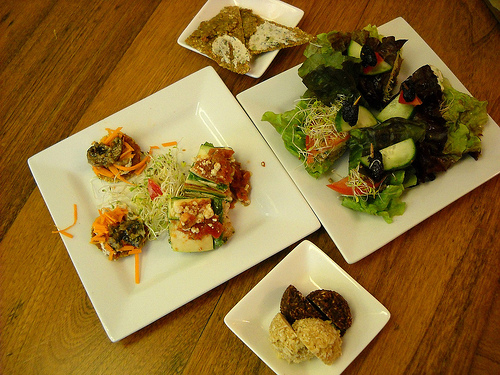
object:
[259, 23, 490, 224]
food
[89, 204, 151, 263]
salad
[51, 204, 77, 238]
carrot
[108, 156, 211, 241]
salad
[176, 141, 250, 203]
food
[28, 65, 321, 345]
plate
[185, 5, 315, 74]
bread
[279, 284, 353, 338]
cookie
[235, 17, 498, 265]
plate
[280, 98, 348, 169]
sprouts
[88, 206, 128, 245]
carrot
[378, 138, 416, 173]
cucumber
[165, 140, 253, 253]
sandwiches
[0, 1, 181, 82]
table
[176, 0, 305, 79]
plate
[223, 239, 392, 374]
plate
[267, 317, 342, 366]
cookies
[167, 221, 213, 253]
slice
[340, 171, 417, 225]
lettuce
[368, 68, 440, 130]
sandwich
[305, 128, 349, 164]
tomato